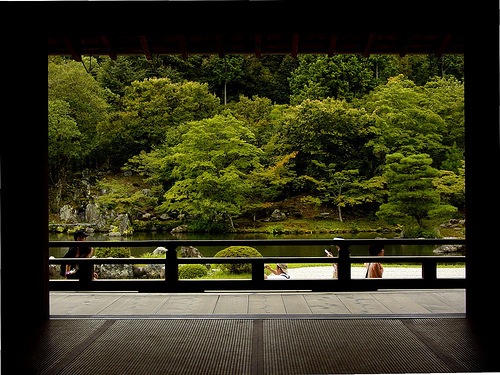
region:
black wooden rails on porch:
[251, 238, 346, 289]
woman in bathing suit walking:
[367, 247, 390, 282]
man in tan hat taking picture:
[261, 260, 296, 282]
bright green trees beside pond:
[379, 75, 461, 234]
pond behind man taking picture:
[272, 231, 310, 261]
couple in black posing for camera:
[64, 233, 94, 284]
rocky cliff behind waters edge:
[76, 187, 135, 234]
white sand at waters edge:
[387, 267, 413, 277]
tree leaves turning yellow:
[268, 148, 304, 174]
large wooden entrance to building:
[38, 47, 470, 374]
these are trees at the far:
[160, 81, 430, 191]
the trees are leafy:
[209, 95, 402, 193]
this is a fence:
[282, 237, 339, 280]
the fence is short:
[283, 238, 351, 293]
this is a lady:
[363, 243, 391, 280]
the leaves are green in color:
[396, 155, 435, 228]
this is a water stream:
[291, 231, 315, 249]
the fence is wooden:
[253, 242, 315, 292]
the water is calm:
[298, 245, 312, 254]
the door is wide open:
[51, 84, 483, 371]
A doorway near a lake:
[13, 28, 498, 344]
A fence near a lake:
[74, 230, 447, 290]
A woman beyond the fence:
[363, 230, 393, 285]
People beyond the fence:
[63, 219, 103, 281]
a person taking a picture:
[257, 258, 292, 283]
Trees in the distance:
[55, 65, 447, 218]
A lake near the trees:
[48, 209, 469, 261]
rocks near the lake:
[60, 196, 137, 237]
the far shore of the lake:
[115, 209, 401, 233]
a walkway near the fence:
[55, 275, 469, 324]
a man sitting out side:
[60, 230, 97, 278]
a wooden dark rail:
[51, 237, 472, 288]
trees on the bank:
[114, 166, 457, 235]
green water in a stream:
[104, 233, 437, 257]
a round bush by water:
[215, 248, 260, 275]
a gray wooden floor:
[48, 286, 460, 311]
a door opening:
[50, 51, 469, 332]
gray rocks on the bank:
[67, 190, 137, 242]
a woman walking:
[364, 244, 385, 283]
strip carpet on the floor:
[47, 319, 464, 368]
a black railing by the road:
[48, 236, 465, 292]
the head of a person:
[71, 228, 93, 245]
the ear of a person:
[73, 233, 80, 242]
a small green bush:
[207, 240, 269, 277]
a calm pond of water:
[48, 219, 461, 279]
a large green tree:
[121, 98, 291, 226]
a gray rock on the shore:
[149, 241, 175, 257]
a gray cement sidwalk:
[46, 287, 465, 318]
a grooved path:
[46, 314, 479, 374]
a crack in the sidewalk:
[240, 289, 255, 317]